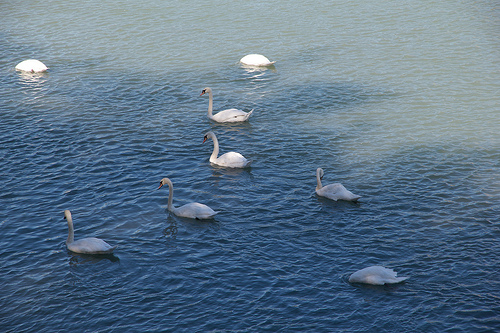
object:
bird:
[311, 166, 362, 205]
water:
[0, 0, 500, 333]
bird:
[13, 57, 49, 77]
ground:
[0, 0, 500, 333]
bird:
[196, 128, 258, 171]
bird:
[237, 52, 278, 67]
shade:
[0, 38, 500, 333]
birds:
[188, 82, 262, 126]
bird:
[152, 175, 220, 222]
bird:
[348, 260, 413, 285]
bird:
[58, 206, 116, 258]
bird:
[348, 264, 411, 290]